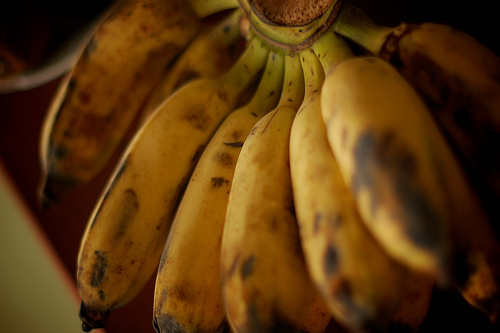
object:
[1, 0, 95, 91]
sink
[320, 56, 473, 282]
banana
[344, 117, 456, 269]
spot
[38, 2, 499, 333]
bananas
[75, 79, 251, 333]
banana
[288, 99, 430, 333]
banana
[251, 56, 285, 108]
banana stem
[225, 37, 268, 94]
banana stem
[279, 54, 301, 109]
banana stem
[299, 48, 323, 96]
banana stem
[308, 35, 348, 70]
banana stem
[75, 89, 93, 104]
black spot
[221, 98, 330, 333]
banana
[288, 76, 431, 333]
banana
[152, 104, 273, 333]
banana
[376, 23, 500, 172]
banana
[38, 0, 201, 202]
banana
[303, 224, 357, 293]
spot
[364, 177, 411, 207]
ground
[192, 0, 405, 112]
bananna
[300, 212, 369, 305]
marks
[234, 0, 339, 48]
stem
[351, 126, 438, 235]
spot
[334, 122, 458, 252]
spots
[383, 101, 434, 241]
banana peel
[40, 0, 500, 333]
bunch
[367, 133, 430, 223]
spot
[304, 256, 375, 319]
spot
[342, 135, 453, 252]
spot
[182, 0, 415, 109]
bushel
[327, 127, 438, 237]
spot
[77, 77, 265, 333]
portion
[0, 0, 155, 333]
section